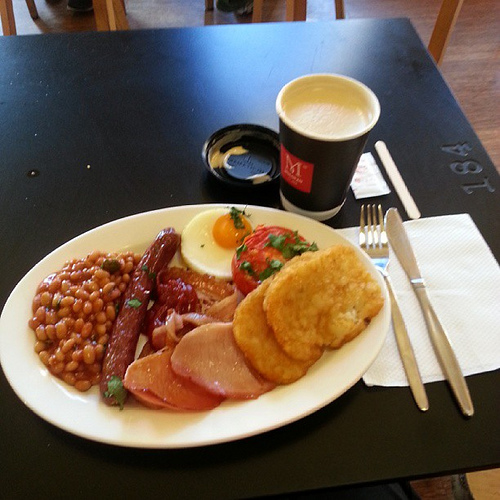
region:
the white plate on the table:
[3, 198, 398, 450]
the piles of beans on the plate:
[37, 256, 101, 366]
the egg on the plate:
[179, 206, 245, 274]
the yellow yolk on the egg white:
[216, 213, 248, 246]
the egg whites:
[183, 210, 235, 278]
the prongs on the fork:
[356, 198, 388, 263]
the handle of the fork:
[378, 269, 429, 410]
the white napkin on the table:
[333, 207, 499, 382]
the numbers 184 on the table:
[439, 135, 492, 198]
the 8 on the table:
[448, 158, 483, 179]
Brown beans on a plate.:
[28, 240, 140, 400]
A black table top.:
[1, 11, 496, 491]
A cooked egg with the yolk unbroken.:
[179, 207, 263, 281]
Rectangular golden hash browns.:
[231, 245, 388, 393]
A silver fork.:
[357, 201, 428, 418]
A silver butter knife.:
[383, 205, 490, 433]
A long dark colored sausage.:
[106, 225, 177, 407]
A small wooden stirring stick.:
[374, 137, 429, 222]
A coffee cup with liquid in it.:
[273, 62, 389, 230]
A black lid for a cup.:
[200, 116, 300, 193]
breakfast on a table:
[13, 76, 478, 451]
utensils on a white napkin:
[352, 206, 487, 429]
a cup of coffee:
[275, 71, 381, 222]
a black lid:
[190, 117, 280, 187]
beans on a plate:
[40, 247, 110, 385]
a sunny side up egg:
[182, 205, 250, 275]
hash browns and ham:
[138, 272, 404, 403]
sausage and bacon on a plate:
[120, 222, 201, 402]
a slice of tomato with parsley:
[240, 221, 305, 273]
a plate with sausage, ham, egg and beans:
[39, 257, 378, 421]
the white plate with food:
[0, 200, 390, 449]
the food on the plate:
[40, 227, 317, 392]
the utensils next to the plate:
[356, 199, 476, 421]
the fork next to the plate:
[359, 202, 427, 415]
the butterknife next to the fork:
[384, 202, 476, 416]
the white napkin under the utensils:
[332, 213, 499, 391]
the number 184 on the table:
[443, 140, 496, 199]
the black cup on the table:
[276, 77, 361, 214]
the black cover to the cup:
[205, 120, 277, 183]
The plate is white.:
[1, 201, 392, 454]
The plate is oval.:
[0, 202, 394, 453]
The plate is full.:
[0, 196, 400, 458]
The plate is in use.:
[0, 195, 400, 455]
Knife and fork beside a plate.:
[0, 197, 498, 454]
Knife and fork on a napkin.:
[328, 196, 498, 421]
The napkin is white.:
[331, 206, 498, 391]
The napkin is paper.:
[325, 209, 499, 396]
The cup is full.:
[276, 62, 381, 222]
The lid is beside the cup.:
[198, 64, 387, 229]